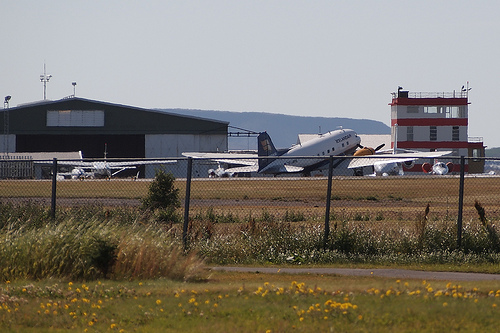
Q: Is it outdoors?
A: Yes, it is outdoors.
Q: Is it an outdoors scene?
A: Yes, it is outdoors.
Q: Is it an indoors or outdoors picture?
A: It is outdoors.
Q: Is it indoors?
A: No, it is outdoors.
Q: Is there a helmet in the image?
A: No, there are no helmets.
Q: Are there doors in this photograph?
A: Yes, there is a door.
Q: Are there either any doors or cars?
A: Yes, there is a door.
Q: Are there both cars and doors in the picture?
A: No, there is a door but no cars.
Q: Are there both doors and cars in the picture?
A: No, there is a door but no cars.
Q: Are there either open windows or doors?
A: Yes, there is an open door.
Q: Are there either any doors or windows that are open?
A: Yes, the door is open.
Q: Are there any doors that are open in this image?
A: Yes, there is an open door.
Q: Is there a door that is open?
A: Yes, there is a door that is open.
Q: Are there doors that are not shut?
A: Yes, there is a open door.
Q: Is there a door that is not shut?
A: Yes, there is a open door.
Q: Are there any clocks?
A: No, there are no clocks.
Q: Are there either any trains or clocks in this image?
A: No, there are no clocks or trains.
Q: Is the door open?
A: Yes, the door is open.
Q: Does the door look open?
A: Yes, the door is open.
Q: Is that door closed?
A: No, the door is open.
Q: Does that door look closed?
A: No, the door is open.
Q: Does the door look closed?
A: No, the door is open.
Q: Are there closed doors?
A: No, there is a door but it is open.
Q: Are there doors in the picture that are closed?
A: No, there is a door but it is open.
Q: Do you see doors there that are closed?
A: No, there is a door but it is open.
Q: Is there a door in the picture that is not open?
A: No, there is a door but it is open.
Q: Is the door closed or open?
A: The door is open.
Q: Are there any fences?
A: Yes, there is a fence.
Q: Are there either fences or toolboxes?
A: Yes, there is a fence.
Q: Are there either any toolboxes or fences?
A: Yes, there is a fence.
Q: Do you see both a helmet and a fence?
A: No, there is a fence but no helmets.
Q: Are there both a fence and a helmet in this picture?
A: No, there is a fence but no helmets.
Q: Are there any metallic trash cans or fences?
A: Yes, there is a metal fence.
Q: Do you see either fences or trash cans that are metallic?
A: Yes, the fence is metallic.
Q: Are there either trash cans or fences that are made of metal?
A: Yes, the fence is made of metal.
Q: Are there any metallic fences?
A: Yes, there is a metal fence.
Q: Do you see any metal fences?
A: Yes, there is a metal fence.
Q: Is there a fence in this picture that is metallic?
A: Yes, there is a fence that is metallic.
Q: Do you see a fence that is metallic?
A: Yes, there is a fence that is metallic.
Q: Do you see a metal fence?
A: Yes, there is a fence that is made of metal.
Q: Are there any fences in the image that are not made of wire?
A: Yes, there is a fence that is made of metal.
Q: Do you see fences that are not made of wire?
A: Yes, there is a fence that is made of metal.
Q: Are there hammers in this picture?
A: No, there are no hammers.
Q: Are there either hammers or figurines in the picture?
A: No, there are no hammers or figurines.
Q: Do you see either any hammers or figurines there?
A: No, there are no hammers or figurines.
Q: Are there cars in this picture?
A: No, there are no cars.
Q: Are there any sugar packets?
A: No, there are no sugar packets.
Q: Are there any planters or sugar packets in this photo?
A: No, there are no sugar packets or planters.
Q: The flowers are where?
A: The flowers are on the grass.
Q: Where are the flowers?
A: The flowers are on the grass.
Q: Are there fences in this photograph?
A: Yes, there is a fence.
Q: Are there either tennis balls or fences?
A: Yes, there is a fence.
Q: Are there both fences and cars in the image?
A: No, there is a fence but no cars.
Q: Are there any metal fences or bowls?
A: Yes, there is a metal fence.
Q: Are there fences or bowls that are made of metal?
A: Yes, the fence is made of metal.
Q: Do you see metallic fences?
A: Yes, there is a metal fence.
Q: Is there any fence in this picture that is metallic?
A: Yes, there is a fence that is metallic.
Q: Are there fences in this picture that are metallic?
A: Yes, there is a fence that is metallic.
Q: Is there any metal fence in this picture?
A: Yes, there is a fence that is made of metal.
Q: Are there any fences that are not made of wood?
A: Yes, there is a fence that is made of metal.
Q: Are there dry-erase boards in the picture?
A: No, there are no dry-erase boards.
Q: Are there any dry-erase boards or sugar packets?
A: No, there are no dry-erase boards or sugar packets.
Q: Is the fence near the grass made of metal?
A: Yes, the fence is made of metal.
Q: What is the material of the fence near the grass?
A: The fence is made of metal.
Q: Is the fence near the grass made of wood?
A: No, the fence is made of metal.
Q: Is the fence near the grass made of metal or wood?
A: The fence is made of metal.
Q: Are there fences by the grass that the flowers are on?
A: Yes, there is a fence by the grass.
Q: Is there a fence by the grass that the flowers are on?
A: Yes, there is a fence by the grass.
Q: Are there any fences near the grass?
A: Yes, there is a fence near the grass.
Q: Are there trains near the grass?
A: No, there is a fence near the grass.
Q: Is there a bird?
A: No, there are no birds.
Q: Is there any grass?
A: Yes, there is grass.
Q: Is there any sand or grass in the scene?
A: Yes, there is grass.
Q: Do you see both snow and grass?
A: No, there is grass but no snow.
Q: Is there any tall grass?
A: Yes, there is tall grass.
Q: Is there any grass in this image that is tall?
A: Yes, there is grass that is tall.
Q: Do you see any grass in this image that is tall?
A: Yes, there is grass that is tall.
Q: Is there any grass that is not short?
A: Yes, there is tall grass.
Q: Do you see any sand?
A: No, there is no sand.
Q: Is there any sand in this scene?
A: No, there is no sand.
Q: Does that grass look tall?
A: Yes, the grass is tall.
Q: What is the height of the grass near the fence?
A: The grass is tall.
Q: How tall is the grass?
A: The grass is tall.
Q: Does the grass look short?
A: No, the grass is tall.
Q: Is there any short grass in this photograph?
A: No, there is grass but it is tall.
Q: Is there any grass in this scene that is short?
A: No, there is grass but it is tall.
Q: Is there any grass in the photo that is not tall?
A: No, there is grass but it is tall.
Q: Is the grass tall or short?
A: The grass is tall.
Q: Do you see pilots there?
A: No, there are no pilots.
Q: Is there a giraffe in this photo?
A: No, there are no giraffes.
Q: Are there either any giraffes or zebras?
A: No, there are no giraffes or zebras.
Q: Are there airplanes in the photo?
A: Yes, there is an airplane.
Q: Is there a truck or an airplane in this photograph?
A: Yes, there is an airplane.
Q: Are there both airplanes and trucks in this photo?
A: No, there is an airplane but no trucks.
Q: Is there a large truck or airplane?
A: Yes, there is a large airplane.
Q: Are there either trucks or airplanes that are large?
A: Yes, the airplane is large.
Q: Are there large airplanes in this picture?
A: Yes, there is a large airplane.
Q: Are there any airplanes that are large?
A: Yes, there is an airplane that is large.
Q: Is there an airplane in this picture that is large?
A: Yes, there is an airplane that is large.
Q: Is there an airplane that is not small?
A: Yes, there is a large airplane.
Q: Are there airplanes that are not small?
A: Yes, there is a large airplane.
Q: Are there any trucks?
A: No, there are no trucks.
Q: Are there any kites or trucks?
A: No, there are no trucks or kites.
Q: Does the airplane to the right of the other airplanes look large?
A: Yes, the plane is large.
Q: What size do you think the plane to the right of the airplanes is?
A: The airplane is large.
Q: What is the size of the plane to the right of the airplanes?
A: The airplane is large.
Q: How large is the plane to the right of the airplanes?
A: The plane is large.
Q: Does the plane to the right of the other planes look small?
A: No, the airplane is large.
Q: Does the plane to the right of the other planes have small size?
A: No, the airplane is large.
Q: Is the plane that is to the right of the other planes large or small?
A: The plane is large.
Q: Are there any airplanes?
A: Yes, there are airplanes.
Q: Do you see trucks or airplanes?
A: Yes, there are airplanes.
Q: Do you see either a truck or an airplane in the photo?
A: Yes, there are airplanes.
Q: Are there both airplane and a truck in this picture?
A: No, there are airplanes but no trucks.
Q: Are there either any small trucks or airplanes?
A: Yes, there are small airplanes.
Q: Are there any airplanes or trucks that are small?
A: Yes, the airplanes are small.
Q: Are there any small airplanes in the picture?
A: Yes, there are small airplanes.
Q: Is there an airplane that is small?
A: Yes, there are airplanes that are small.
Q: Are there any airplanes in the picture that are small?
A: Yes, there are airplanes that are small.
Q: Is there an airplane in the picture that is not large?
A: Yes, there are small airplanes.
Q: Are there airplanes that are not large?
A: Yes, there are small airplanes.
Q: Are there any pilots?
A: No, there are no pilots.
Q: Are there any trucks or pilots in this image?
A: No, there are no pilots or trucks.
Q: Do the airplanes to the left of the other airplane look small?
A: Yes, the planes are small.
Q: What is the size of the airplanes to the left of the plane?
A: The airplanes are small.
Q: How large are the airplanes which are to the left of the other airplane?
A: The airplanes are small.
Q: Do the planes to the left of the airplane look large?
A: No, the planes are small.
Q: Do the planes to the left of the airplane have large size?
A: No, the planes are small.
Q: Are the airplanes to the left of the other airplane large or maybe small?
A: The airplanes are small.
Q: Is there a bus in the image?
A: No, there are no buses.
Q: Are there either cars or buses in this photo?
A: No, there are no buses or cars.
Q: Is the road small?
A: Yes, the road is small.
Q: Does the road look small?
A: Yes, the road is small.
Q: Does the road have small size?
A: Yes, the road is small.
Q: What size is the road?
A: The road is small.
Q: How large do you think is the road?
A: The road is small.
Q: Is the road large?
A: No, the road is small.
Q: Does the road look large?
A: No, the road is small.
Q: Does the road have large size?
A: No, the road is small.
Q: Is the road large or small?
A: The road is small.